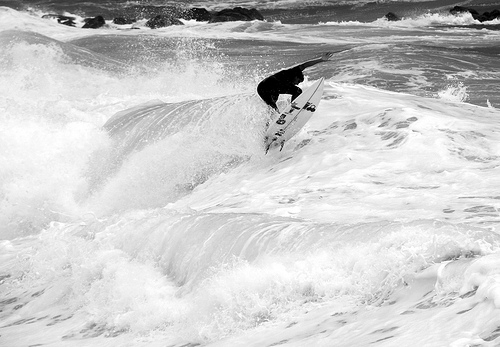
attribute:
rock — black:
[82, 12, 107, 24]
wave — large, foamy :
[86, 216, 483, 344]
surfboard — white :
[264, 77, 329, 155]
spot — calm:
[168, 24, 489, 105]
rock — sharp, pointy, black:
[378, 11, 403, 23]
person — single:
[257, 49, 333, 113]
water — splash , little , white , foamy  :
[0, 1, 499, 345]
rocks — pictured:
[90, 0, 375, 55]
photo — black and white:
[3, 1, 498, 343]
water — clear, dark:
[136, 9, 280, 110]